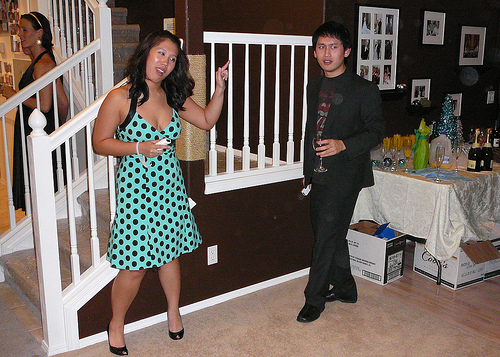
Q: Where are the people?
A: Basement.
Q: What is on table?
A: Tablecloth.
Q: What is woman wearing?
A: Dress.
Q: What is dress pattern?
A: Polka dot.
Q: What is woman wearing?
A: Dress.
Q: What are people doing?
A: Dancing.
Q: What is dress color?
A: Teal.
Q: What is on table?
A: Refreshments.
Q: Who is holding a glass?
A: A man.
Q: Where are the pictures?
A: Wall.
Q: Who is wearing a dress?
A: A lady.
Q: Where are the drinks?
A: Table.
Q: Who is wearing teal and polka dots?
A: A lady.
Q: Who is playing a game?
A: The people.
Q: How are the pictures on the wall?
A: Hanging.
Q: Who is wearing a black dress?
A: A lady.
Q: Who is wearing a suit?
A: A man.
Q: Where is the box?
A: On floor.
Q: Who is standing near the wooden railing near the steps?
A: Woman wearing blue and black dress.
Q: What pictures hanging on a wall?
A: The three picture in white frame.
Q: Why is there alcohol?
A: For a party.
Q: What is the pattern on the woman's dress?
A: Polka dots.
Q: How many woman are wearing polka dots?
A: One.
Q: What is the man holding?
A: Glass.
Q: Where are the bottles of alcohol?
A: On the table.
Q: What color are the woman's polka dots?
A: Black.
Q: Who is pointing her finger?
A: The woman in polka dots.